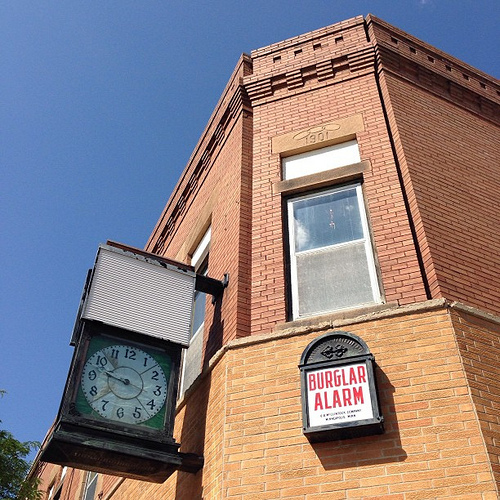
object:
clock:
[36, 322, 191, 487]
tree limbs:
[0, 424, 49, 500]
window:
[277, 172, 387, 324]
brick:
[340, 464, 387, 482]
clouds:
[410, 0, 500, 34]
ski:
[0, 0, 500, 500]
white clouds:
[410, 0, 436, 13]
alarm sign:
[296, 327, 388, 439]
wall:
[217, 13, 500, 500]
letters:
[314, 392, 323, 411]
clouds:
[0, 0, 149, 237]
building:
[0, 5, 500, 500]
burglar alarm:
[306, 363, 370, 411]